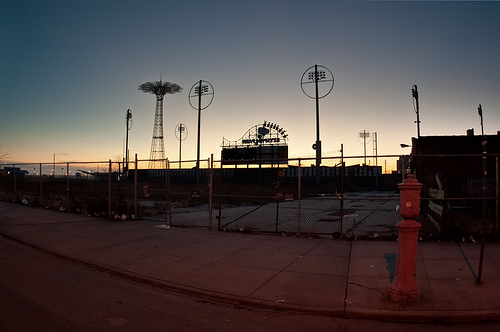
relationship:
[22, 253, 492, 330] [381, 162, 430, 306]
street beside fire hydrant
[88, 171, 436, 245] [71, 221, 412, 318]
fencing running along sidewalk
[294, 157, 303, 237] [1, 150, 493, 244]
post holding up fence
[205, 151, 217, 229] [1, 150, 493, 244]
post holding up fence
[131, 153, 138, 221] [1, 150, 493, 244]
post holding up fence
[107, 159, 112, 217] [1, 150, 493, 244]
post holding up fence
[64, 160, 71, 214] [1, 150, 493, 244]
post holding up fence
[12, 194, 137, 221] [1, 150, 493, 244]
trash along fence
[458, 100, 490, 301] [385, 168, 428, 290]
pole next to fire hydrant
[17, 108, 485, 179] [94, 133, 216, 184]
sunset visible in sky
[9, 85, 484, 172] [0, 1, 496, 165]
sunset visible in sky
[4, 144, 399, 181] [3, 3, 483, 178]
sunset visible in sky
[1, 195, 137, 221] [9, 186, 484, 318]
trash on ground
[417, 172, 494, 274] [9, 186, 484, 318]
trash on ground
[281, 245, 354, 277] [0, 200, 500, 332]
square on road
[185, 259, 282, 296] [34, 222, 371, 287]
cement square on sidewalk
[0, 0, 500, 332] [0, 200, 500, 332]
square on road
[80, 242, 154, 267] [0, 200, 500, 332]
cement square on road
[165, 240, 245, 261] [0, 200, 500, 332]
cement square on road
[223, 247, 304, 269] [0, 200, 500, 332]
cement square on road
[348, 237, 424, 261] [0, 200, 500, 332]
cement square on road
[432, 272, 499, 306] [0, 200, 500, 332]
cement square on road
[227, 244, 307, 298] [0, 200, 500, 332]
cement square on road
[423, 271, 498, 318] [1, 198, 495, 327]
square on sidewalk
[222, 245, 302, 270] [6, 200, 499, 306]
square on sidewalk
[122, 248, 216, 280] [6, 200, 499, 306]
square on sidewalk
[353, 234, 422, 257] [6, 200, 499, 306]
square on sidewalk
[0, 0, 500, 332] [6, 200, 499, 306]
square on sidewalk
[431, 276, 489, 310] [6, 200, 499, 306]
square on sidewalk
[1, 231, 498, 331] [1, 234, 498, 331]
curb along street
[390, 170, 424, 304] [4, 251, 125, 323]
structure on side of road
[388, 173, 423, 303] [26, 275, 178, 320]
structure on side of street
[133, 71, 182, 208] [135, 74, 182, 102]
tower has top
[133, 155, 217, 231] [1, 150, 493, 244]
gate of fence